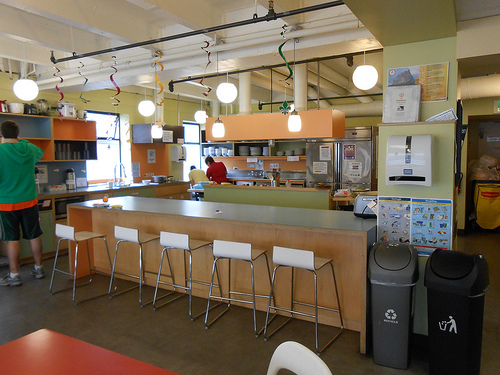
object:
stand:
[327, 189, 342, 210]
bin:
[366, 239, 420, 370]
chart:
[374, 195, 450, 258]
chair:
[266, 244, 336, 335]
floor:
[0, 231, 499, 374]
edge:
[64, 202, 82, 278]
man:
[0, 121, 46, 287]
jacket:
[1, 141, 46, 205]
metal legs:
[312, 272, 320, 355]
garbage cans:
[421, 246, 485, 374]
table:
[0, 326, 195, 374]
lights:
[134, 99, 155, 117]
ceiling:
[0, 0, 499, 103]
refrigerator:
[306, 126, 375, 188]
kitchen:
[98, 107, 377, 211]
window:
[82, 109, 131, 185]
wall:
[0, 72, 248, 124]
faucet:
[111, 164, 129, 183]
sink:
[99, 185, 144, 195]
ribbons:
[50, 64, 68, 105]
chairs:
[261, 246, 344, 356]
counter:
[64, 189, 376, 239]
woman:
[204, 156, 228, 182]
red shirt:
[205, 161, 238, 184]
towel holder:
[385, 133, 432, 187]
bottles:
[57, 142, 67, 160]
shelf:
[55, 117, 98, 163]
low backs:
[272, 244, 315, 271]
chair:
[150, 229, 219, 321]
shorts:
[0, 205, 45, 241]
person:
[185, 165, 208, 183]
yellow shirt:
[188, 168, 208, 186]